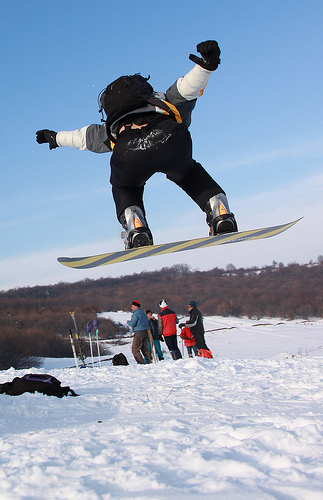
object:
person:
[179, 300, 210, 354]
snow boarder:
[37, 41, 236, 252]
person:
[157, 299, 182, 362]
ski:
[147, 325, 157, 363]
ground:
[0, 311, 322, 499]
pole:
[95, 329, 102, 369]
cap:
[132, 300, 140, 308]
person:
[127, 300, 152, 363]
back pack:
[97, 72, 154, 125]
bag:
[1, 373, 78, 398]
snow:
[1, 313, 322, 499]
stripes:
[27, 373, 53, 384]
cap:
[188, 300, 196, 308]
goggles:
[187, 305, 192, 308]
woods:
[0, 255, 322, 372]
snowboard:
[57, 217, 304, 269]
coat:
[180, 327, 196, 347]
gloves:
[86, 320, 92, 333]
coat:
[127, 307, 149, 331]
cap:
[158, 298, 168, 308]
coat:
[183, 307, 204, 334]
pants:
[143, 338, 163, 359]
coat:
[147, 317, 164, 342]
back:
[106, 91, 171, 136]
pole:
[68, 328, 78, 369]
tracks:
[163, 409, 208, 417]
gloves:
[188, 40, 221, 71]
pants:
[110, 118, 225, 225]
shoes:
[120, 202, 152, 250]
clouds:
[2, 253, 51, 290]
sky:
[0, 0, 322, 293]